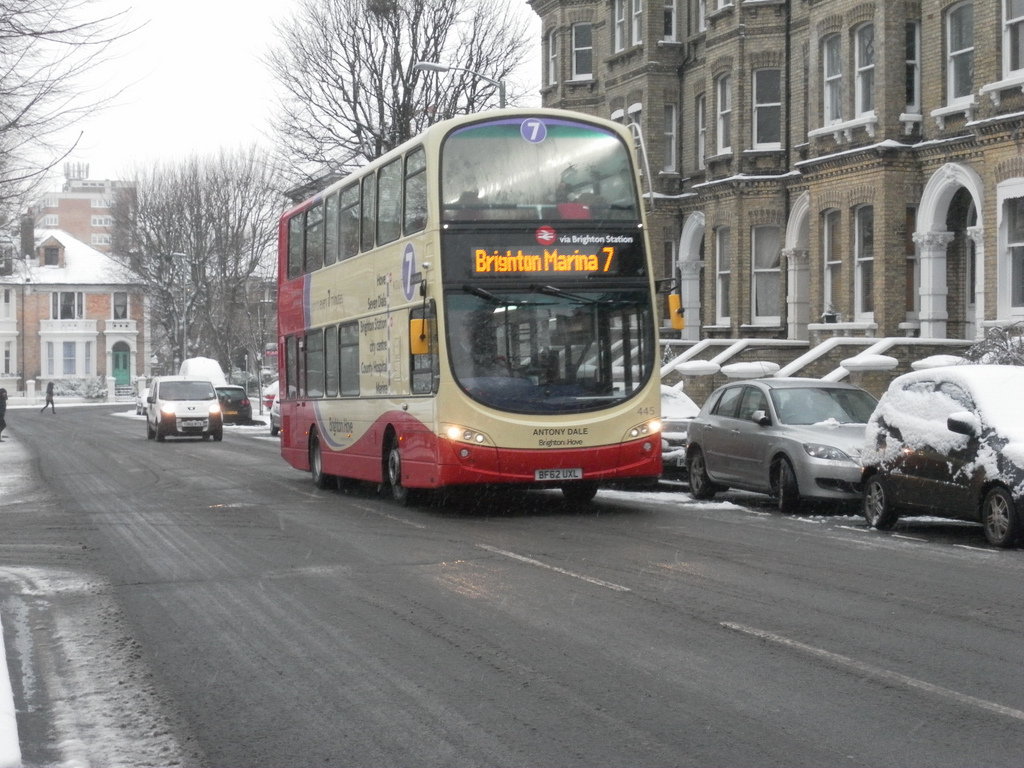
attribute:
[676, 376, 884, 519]
car — silver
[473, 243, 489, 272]
letter — gold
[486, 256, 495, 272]
letter — gold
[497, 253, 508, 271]
letter — gold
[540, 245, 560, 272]
letter — gold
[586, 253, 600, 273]
letter — gold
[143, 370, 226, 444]
car — white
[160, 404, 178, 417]
headlight — white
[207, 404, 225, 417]
headlight — white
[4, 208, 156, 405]
building — red, brick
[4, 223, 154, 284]
roof — white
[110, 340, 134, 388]
door — green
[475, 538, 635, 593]
line — white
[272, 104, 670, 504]
bus — double decker, red, off-white, double-decker, tan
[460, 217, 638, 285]
letters — orange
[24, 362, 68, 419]
person — walking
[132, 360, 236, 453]
van — white, activated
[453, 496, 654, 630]
line — white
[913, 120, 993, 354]
arch — white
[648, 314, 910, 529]
car — parked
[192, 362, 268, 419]
car — parked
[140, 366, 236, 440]
van — white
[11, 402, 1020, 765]
street — slushy, snowy